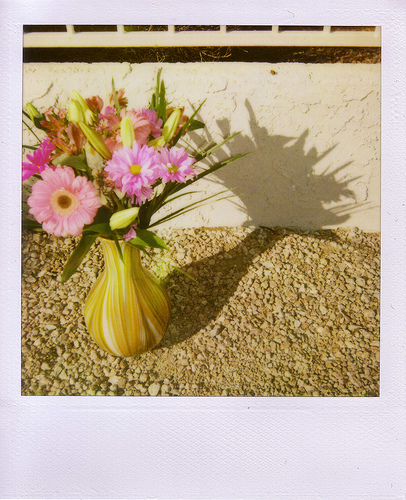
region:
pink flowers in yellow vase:
[22, 68, 230, 342]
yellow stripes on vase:
[83, 235, 171, 354]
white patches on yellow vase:
[90, 262, 162, 349]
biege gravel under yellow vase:
[24, 232, 377, 390]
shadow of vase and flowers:
[160, 131, 354, 338]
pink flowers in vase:
[27, 98, 194, 230]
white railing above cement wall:
[26, 25, 377, 48]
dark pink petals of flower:
[23, 136, 55, 174]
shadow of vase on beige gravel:
[150, 227, 288, 339]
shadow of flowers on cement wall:
[195, 99, 352, 240]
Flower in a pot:
[23, 65, 250, 359]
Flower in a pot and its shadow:
[20, 66, 368, 352]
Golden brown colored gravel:
[22, 226, 377, 395]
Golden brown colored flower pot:
[73, 234, 172, 359]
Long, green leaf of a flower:
[54, 232, 104, 290]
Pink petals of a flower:
[32, 188, 52, 221]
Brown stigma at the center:
[60, 195, 69, 206]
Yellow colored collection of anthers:
[51, 194, 58, 209]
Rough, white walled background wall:
[22, 66, 382, 229]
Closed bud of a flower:
[108, 199, 143, 229]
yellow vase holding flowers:
[73, 213, 176, 356]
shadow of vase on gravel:
[139, 213, 272, 337]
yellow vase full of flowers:
[28, 68, 227, 362]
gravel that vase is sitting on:
[28, 233, 380, 397]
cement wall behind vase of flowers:
[28, 61, 373, 229]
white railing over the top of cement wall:
[26, 28, 375, 50]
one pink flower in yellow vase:
[26, 164, 103, 237]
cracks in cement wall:
[33, 64, 375, 223]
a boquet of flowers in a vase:
[29, 99, 226, 357]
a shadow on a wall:
[204, 120, 360, 231]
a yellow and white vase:
[80, 240, 175, 358]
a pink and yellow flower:
[24, 169, 106, 239]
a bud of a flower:
[157, 106, 194, 147]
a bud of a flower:
[108, 205, 142, 231]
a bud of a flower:
[80, 126, 113, 160]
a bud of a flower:
[118, 116, 137, 150]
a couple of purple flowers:
[102, 146, 197, 192]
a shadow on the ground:
[165, 248, 246, 325]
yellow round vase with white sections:
[79, 235, 171, 350]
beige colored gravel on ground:
[22, 232, 379, 394]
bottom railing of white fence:
[24, 33, 379, 53]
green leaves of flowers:
[63, 229, 173, 279]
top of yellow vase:
[95, 233, 136, 267]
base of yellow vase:
[78, 275, 173, 353]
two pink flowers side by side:
[106, 131, 190, 193]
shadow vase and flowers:
[126, 95, 335, 354]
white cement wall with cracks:
[23, 61, 377, 222]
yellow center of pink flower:
[128, 162, 140, 174]